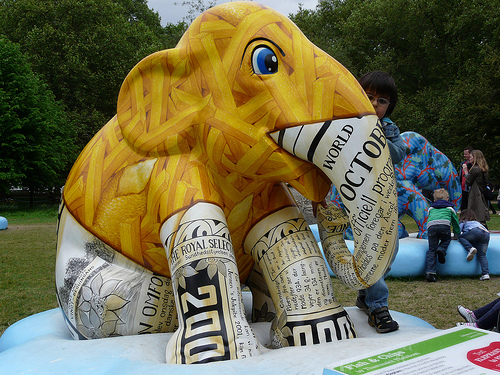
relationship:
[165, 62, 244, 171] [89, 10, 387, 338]
pattern on elephant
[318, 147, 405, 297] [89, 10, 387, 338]
trunk on elephant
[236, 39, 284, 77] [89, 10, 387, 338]
eyes on elephant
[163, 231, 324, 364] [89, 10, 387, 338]
legs on elephant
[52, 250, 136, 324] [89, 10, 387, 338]
diaper on elephant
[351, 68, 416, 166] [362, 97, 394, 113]
child wearing glasses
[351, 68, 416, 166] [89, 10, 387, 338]
child by elephant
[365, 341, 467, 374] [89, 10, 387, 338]
sign by elephant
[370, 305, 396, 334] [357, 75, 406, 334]
shoe on child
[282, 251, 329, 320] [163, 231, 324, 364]
words on legs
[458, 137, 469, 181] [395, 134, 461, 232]
man by sculpture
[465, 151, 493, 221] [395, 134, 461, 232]
woman by sculpture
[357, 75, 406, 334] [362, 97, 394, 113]
child wearing glasses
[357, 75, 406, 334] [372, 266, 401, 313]
child wearing jeans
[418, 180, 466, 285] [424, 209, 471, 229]
boy wearing sweater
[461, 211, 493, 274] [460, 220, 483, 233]
girl wearing shirt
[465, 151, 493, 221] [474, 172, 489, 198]
woman wearing coat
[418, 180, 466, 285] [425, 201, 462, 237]
boy with sweater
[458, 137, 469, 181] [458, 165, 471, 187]
man wearing shirt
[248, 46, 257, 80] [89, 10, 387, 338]
eyelashes on elephant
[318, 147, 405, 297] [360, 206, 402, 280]
trunk has writing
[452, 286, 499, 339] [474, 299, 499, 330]
person wearing pants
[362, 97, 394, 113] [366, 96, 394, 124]
glasses on face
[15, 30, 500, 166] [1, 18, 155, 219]
forest with trees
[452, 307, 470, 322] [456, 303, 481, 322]
sole of shoe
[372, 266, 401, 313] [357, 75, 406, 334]
jeans of child